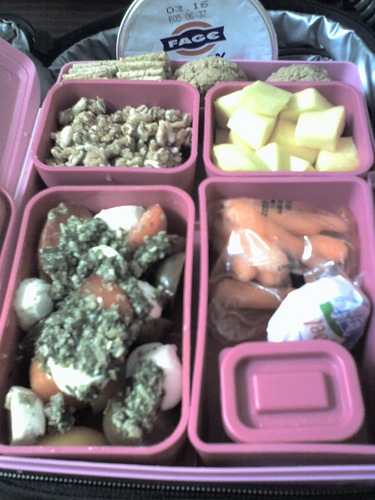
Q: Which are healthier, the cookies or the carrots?
A: The carrots are healthier than the cookies.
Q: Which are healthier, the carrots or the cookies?
A: The carrots are healthier than the cookies.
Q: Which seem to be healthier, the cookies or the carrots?
A: The carrots are healthier than the cookies.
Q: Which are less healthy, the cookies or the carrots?
A: The cookies are less healthy than the carrots.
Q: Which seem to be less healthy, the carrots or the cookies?
A: The cookies are less healthy than the carrots.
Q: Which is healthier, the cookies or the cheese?
A: The cheese is healthier than the cookies.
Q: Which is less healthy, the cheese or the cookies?
A: The cookies is less healthy than the cheese.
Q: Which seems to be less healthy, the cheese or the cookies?
A: The cookies is less healthy than the cheese.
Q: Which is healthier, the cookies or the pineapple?
A: The pineapple is healthier than the cookies.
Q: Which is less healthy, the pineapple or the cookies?
A: The cookies is less healthy than the pineapple.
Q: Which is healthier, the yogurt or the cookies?
A: The yogurt is healthier than the cookies.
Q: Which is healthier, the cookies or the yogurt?
A: The yogurt is healthier than the cookies.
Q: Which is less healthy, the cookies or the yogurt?
A: The cookies is less healthy than the yogurt.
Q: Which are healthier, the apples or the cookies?
A: The apples are healthier than the cookies.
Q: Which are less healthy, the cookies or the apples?
A: The cookies are less healthy than the apples.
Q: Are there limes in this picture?
A: No, there are no limes.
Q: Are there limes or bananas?
A: No, there are no limes or bananas.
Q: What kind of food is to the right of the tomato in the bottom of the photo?
A: The food is mozzarella.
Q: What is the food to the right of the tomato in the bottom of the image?
A: The food is mozzarella.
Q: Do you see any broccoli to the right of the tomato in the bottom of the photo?
A: No, there is mozzarella to the right of the tomato.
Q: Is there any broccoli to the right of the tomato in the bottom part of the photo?
A: No, there is mozzarella to the right of the tomato.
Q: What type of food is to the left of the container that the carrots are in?
A: The food is mozzarella.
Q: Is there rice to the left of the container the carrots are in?
A: No, there is mozzarella to the left of the container.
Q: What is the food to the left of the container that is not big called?
A: The food is mozzarella.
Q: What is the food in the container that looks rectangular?
A: The food is mozzarella.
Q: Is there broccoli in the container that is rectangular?
A: No, there is mozzarella in the container.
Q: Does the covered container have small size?
A: Yes, the container is small.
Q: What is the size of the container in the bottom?
A: The container is small.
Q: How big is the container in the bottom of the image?
A: The container is small.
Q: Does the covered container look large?
A: No, the container is small.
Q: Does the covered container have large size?
A: No, the container is small.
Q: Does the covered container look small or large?
A: The container is small.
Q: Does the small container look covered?
A: Yes, the container is covered.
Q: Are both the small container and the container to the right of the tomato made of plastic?
A: Yes, both the container and the container are made of plastic.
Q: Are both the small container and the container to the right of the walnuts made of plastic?
A: Yes, both the container and the container are made of plastic.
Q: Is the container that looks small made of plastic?
A: Yes, the container is made of plastic.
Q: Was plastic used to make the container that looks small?
A: Yes, the container is made of plastic.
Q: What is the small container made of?
A: The container is made of plastic.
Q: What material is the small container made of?
A: The container is made of plastic.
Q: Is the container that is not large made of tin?
A: No, the container is made of plastic.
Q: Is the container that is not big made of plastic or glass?
A: The container is made of plastic.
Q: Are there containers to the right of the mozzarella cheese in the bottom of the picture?
A: Yes, there is a container to the right of the mozzarella.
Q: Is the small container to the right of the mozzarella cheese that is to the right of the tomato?
A: Yes, the container is to the right of the mozzarella cheese.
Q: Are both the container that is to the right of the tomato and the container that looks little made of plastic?
A: Yes, both the container and the container are made of plastic.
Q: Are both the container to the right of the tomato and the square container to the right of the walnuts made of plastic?
A: Yes, both the container and the container are made of plastic.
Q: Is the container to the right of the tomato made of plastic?
A: Yes, the container is made of plastic.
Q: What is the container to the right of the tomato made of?
A: The container is made of plastic.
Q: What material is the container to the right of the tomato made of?
A: The container is made of plastic.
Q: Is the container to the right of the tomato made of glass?
A: No, the container is made of plastic.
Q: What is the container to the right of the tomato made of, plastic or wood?
A: The container is made of plastic.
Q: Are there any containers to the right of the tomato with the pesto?
A: Yes, there is a container to the right of the tomato.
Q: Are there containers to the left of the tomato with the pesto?
A: No, the container is to the right of the tomato.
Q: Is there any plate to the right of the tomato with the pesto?
A: No, there is a container to the right of the tomato.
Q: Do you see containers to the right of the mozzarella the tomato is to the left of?
A: Yes, there is a container to the right of the mozzarella cheese.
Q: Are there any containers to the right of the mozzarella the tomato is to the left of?
A: Yes, there is a container to the right of the mozzarella cheese.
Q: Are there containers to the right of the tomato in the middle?
A: Yes, there is a container to the right of the tomato.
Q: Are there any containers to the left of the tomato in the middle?
A: No, the container is to the right of the tomato.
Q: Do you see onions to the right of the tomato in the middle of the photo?
A: No, there is a container to the right of the tomato.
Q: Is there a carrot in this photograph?
A: Yes, there are carrots.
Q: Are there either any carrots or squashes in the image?
A: Yes, there are carrots.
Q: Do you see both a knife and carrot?
A: No, there are carrots but no knives.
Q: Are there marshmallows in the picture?
A: No, there are no marshmallows.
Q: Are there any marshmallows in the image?
A: No, there are no marshmallows.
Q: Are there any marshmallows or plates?
A: No, there are no marshmallows or plates.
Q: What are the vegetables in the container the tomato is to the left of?
A: The vegetables are carrots.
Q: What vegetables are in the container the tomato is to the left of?
A: The vegetables are carrots.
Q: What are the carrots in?
A: The carrots are in the container.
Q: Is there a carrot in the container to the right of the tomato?
A: Yes, there are carrots in the container.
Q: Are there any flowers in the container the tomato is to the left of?
A: No, there are carrots in the container.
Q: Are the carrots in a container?
A: Yes, the carrots are in a container.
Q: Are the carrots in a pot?
A: No, the carrots are in a container.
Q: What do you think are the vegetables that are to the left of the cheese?
A: The vegetables are carrots.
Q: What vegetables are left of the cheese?
A: The vegetables are carrots.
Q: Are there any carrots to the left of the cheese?
A: Yes, there are carrots to the left of the cheese.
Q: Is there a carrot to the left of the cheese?
A: Yes, there are carrots to the left of the cheese.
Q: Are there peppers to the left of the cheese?
A: No, there are carrots to the left of the cheese.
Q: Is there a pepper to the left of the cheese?
A: No, there are carrots to the left of the cheese.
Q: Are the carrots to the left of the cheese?
A: Yes, the carrots are to the left of the cheese.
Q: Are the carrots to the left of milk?
A: No, the carrots are to the left of the cheese.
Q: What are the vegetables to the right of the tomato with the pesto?
A: The vegetables are carrots.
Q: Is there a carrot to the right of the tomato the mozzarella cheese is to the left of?
A: Yes, there are carrots to the right of the tomato.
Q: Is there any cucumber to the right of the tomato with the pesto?
A: No, there are carrots to the right of the tomato.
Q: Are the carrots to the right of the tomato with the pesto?
A: Yes, the carrots are to the right of the tomato.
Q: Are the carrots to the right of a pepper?
A: No, the carrots are to the right of the tomato.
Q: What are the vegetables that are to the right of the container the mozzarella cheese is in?
A: The vegetables are carrots.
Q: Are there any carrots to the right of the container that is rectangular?
A: Yes, there are carrots to the right of the container.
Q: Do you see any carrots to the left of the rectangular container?
A: No, the carrots are to the right of the container.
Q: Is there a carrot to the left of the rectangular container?
A: No, the carrots are to the right of the container.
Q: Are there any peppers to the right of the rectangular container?
A: No, there are carrots to the right of the container.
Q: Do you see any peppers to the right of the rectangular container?
A: No, there are carrots to the right of the container.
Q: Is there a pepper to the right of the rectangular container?
A: No, there are carrots to the right of the container.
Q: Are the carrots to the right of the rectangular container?
A: Yes, the carrots are to the right of the container.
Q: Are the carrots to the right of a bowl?
A: No, the carrots are to the right of the container.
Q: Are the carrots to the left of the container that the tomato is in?
A: No, the carrots are to the right of the container.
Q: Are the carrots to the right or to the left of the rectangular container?
A: The carrots are to the right of the container.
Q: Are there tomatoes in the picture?
A: Yes, there is a tomato.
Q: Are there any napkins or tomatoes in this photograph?
A: Yes, there is a tomato.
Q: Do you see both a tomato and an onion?
A: No, there is a tomato but no onions.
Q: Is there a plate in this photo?
A: No, there are no plates.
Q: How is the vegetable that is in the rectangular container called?
A: The vegetable is a tomato.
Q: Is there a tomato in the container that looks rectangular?
A: Yes, there is a tomato in the container.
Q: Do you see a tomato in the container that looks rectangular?
A: Yes, there is a tomato in the container.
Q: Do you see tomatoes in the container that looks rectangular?
A: Yes, there is a tomato in the container.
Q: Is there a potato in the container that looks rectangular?
A: No, there is a tomato in the container.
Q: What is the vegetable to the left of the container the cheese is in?
A: The vegetable is a tomato.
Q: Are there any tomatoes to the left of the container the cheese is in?
A: Yes, there is a tomato to the left of the container.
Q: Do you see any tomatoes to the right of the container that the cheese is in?
A: No, the tomato is to the left of the container.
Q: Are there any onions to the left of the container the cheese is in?
A: No, there is a tomato to the left of the container.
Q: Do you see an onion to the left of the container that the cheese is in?
A: No, there is a tomato to the left of the container.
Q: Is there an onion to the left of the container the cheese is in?
A: No, there is a tomato to the left of the container.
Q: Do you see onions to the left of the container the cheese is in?
A: No, there is a tomato to the left of the container.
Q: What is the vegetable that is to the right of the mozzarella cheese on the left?
A: The vegetable is a tomato.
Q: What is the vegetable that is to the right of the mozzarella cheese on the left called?
A: The vegetable is a tomato.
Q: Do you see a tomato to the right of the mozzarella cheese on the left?
A: Yes, there is a tomato to the right of the mozzarella.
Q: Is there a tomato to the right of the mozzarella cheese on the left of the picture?
A: Yes, there is a tomato to the right of the mozzarella.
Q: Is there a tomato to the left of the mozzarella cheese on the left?
A: No, the tomato is to the right of the mozzarella.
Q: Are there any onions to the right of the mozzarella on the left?
A: No, there is a tomato to the right of the mozzarella.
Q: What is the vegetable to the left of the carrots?
A: The vegetable is a tomato.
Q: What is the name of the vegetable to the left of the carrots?
A: The vegetable is a tomato.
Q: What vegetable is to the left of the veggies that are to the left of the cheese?
A: The vegetable is a tomato.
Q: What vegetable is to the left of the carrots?
A: The vegetable is a tomato.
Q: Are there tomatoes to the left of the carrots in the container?
A: Yes, there is a tomato to the left of the carrots.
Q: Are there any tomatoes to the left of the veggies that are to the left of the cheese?
A: Yes, there is a tomato to the left of the carrots.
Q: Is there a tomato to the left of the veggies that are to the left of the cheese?
A: Yes, there is a tomato to the left of the carrots.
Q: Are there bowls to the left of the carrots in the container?
A: No, there is a tomato to the left of the carrots.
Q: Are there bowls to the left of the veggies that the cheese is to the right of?
A: No, there is a tomato to the left of the carrots.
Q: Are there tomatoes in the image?
A: Yes, there is a tomato.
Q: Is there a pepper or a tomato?
A: Yes, there is a tomato.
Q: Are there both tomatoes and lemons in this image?
A: No, there is a tomato but no lemons.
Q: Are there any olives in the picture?
A: No, there are no olives.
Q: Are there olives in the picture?
A: No, there are no olives.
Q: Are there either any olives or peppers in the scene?
A: No, there are no olives or peppers.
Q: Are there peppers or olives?
A: No, there are no olives or peppers.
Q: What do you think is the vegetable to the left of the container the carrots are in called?
A: The vegetable is a tomato.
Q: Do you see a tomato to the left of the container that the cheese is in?
A: Yes, there is a tomato to the left of the container.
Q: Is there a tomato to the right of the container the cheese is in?
A: No, the tomato is to the left of the container.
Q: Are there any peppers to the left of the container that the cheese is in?
A: No, there is a tomato to the left of the container.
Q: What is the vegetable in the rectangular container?
A: The vegetable is a tomato.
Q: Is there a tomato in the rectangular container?
A: Yes, there is a tomato in the container.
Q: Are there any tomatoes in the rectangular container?
A: Yes, there is a tomato in the container.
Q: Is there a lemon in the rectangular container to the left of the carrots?
A: No, there is a tomato in the container.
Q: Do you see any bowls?
A: No, there are no bowls.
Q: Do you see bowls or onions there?
A: No, there are no bowls or onions.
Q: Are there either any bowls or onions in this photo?
A: No, there are no bowls or onions.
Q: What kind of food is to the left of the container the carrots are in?
A: The food is mozzarella.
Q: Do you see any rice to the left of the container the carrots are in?
A: No, there is mozzarella to the left of the container.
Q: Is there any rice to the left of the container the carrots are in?
A: No, there is mozzarella to the left of the container.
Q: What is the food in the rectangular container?
A: The food is mozzarella.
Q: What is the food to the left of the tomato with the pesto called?
A: The food is mozzarella.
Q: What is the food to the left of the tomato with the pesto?
A: The food is mozzarella.